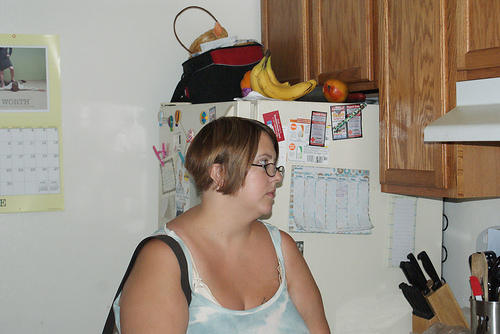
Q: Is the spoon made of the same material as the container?
A: Yes, both the spoon and the container are made of wood.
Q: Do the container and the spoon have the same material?
A: Yes, both the container and the spoon are made of wood.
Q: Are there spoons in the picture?
A: Yes, there is a spoon.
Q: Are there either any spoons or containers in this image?
A: Yes, there is a spoon.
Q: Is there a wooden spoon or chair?
A: Yes, there is a wood spoon.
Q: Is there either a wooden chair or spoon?
A: Yes, there is a wood spoon.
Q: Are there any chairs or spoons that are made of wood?
A: Yes, the spoon is made of wood.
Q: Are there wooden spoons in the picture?
A: Yes, there is a wood spoon.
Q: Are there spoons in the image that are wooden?
A: Yes, there is a spoon that is wooden.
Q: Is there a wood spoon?
A: Yes, there is a spoon that is made of wood.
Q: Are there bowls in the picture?
A: No, there are no bowls.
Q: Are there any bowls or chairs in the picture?
A: No, there are no bowls or chairs.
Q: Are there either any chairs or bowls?
A: No, there are no bowls or chairs.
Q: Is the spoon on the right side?
A: Yes, the spoon is on the right of the image.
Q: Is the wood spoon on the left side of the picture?
A: No, the spoon is on the right of the image.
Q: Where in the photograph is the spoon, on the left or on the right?
A: The spoon is on the right of the image.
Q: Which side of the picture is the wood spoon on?
A: The spoon is on the right of the image.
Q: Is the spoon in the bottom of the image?
A: Yes, the spoon is in the bottom of the image.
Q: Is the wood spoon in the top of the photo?
A: No, the spoon is in the bottom of the image.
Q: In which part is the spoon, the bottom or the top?
A: The spoon is in the bottom of the image.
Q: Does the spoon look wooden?
A: Yes, the spoon is wooden.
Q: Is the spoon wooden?
A: Yes, the spoon is wooden.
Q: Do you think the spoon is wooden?
A: Yes, the spoon is wooden.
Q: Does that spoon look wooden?
A: Yes, the spoon is wooden.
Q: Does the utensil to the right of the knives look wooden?
A: Yes, the spoon is wooden.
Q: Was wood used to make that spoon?
A: Yes, the spoon is made of wood.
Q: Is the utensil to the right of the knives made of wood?
A: Yes, the spoon is made of wood.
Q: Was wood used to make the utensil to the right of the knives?
A: Yes, the spoon is made of wood.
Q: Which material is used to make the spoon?
A: The spoon is made of wood.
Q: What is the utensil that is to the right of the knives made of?
A: The spoon is made of wood.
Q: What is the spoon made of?
A: The spoon is made of wood.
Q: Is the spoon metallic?
A: No, the spoon is wooden.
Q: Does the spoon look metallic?
A: No, the spoon is wooden.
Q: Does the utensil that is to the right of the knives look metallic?
A: No, the spoon is wooden.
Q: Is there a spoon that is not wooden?
A: No, there is a spoon but it is wooden.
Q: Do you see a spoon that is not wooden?
A: No, there is a spoon but it is wooden.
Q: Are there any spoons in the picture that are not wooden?
A: No, there is a spoon but it is wooden.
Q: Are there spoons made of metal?
A: No, there is a spoon but it is made of wood.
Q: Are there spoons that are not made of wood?
A: No, there is a spoon but it is made of wood.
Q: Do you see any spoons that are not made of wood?
A: No, there is a spoon but it is made of wood.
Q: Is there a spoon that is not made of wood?
A: No, there is a spoon but it is made of wood.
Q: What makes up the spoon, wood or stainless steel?
A: The spoon is made of wood.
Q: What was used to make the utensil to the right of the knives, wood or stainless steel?
A: The spoon is made of wood.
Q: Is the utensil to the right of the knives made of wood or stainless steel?
A: The spoon is made of wood.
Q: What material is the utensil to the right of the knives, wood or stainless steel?
A: The spoon is made of wood.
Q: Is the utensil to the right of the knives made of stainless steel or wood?
A: The spoon is made of wood.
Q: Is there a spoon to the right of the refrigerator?
A: Yes, there is a spoon to the right of the refrigerator.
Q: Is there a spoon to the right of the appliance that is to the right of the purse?
A: Yes, there is a spoon to the right of the refrigerator.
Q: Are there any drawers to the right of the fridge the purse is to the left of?
A: No, there is a spoon to the right of the freezer.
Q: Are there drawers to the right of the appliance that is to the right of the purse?
A: No, there is a spoon to the right of the freezer.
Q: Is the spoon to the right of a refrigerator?
A: Yes, the spoon is to the right of a refrigerator.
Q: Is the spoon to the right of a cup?
A: No, the spoon is to the right of a refrigerator.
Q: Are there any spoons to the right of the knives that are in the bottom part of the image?
A: Yes, there is a spoon to the right of the knives.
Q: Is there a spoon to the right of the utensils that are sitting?
A: Yes, there is a spoon to the right of the knives.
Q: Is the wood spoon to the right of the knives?
A: Yes, the spoon is to the right of the knives.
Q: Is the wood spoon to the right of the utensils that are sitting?
A: Yes, the spoon is to the right of the knives.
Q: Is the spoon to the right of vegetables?
A: No, the spoon is to the right of the knives.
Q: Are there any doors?
A: Yes, there is a door.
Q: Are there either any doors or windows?
A: Yes, there is a door.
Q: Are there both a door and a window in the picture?
A: No, there is a door but no windows.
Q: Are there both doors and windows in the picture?
A: No, there is a door but no windows.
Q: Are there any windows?
A: No, there are no windows.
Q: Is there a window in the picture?
A: No, there are no windows.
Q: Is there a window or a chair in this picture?
A: No, there are no windows or chairs.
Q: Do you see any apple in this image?
A: Yes, there is an apple.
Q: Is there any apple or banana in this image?
A: Yes, there is an apple.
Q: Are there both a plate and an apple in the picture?
A: No, there is an apple but no plates.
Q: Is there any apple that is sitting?
A: Yes, there is an apple that is sitting.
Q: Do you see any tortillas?
A: No, there are no tortillas.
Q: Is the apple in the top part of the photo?
A: Yes, the apple is in the top of the image.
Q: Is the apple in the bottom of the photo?
A: No, the apple is in the top of the image.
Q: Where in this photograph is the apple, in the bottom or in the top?
A: The apple is in the top of the image.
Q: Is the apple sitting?
A: Yes, the apple is sitting.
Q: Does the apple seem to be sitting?
A: Yes, the apple is sitting.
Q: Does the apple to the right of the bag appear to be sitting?
A: Yes, the apple is sitting.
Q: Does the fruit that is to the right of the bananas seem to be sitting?
A: Yes, the apple is sitting.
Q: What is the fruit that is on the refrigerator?
A: The fruit is an apple.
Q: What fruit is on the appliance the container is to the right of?
A: The fruit is an apple.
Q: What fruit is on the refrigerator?
A: The fruit is an apple.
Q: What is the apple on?
A: The apple is on the refrigerator.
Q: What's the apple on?
A: The apple is on the refrigerator.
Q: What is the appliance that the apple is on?
A: The appliance is a refrigerator.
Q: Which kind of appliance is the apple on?
A: The apple is on the refrigerator.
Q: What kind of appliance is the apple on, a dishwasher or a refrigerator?
A: The apple is on a refrigerator.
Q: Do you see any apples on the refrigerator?
A: Yes, there is an apple on the refrigerator.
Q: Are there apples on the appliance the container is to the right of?
A: Yes, there is an apple on the refrigerator.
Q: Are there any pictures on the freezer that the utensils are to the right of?
A: No, there is an apple on the refrigerator.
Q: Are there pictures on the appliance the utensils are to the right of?
A: No, there is an apple on the refrigerator.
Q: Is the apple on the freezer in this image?
A: Yes, the apple is on the freezer.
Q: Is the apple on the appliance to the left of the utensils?
A: Yes, the apple is on the freezer.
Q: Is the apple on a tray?
A: No, the apple is on the freezer.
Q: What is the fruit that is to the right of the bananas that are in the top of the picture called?
A: The fruit is an apple.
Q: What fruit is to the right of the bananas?
A: The fruit is an apple.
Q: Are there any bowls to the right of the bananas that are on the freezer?
A: No, there is an apple to the right of the bananas.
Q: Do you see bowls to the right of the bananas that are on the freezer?
A: No, there is an apple to the right of the bananas.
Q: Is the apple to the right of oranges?
A: No, the apple is to the right of the bananas.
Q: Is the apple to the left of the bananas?
A: No, the apple is to the right of the bananas.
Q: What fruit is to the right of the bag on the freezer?
A: The fruit is an apple.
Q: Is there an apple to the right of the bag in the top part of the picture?
A: Yes, there is an apple to the right of the bag.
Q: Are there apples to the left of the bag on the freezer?
A: No, the apple is to the right of the bag.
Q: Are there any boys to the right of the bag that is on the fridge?
A: No, there is an apple to the right of the bag.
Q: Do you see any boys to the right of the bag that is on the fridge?
A: No, there is an apple to the right of the bag.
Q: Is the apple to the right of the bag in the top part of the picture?
A: Yes, the apple is to the right of the bag.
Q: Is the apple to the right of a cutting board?
A: No, the apple is to the right of the bag.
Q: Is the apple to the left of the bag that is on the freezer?
A: No, the apple is to the right of the bag.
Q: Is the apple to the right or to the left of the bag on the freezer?
A: The apple is to the right of the bag.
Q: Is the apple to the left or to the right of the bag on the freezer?
A: The apple is to the right of the bag.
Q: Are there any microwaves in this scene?
A: No, there are no microwaves.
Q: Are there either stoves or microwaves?
A: No, there are no microwaves or stoves.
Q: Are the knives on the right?
A: Yes, the knives are on the right of the image.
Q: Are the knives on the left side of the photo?
A: No, the knives are on the right of the image.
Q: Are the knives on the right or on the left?
A: The knives are on the right of the image.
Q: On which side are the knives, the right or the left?
A: The knives are on the right of the image.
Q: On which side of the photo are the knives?
A: The knives are on the right of the image.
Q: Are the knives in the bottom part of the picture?
A: Yes, the knives are in the bottom of the image.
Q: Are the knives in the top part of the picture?
A: No, the knives are in the bottom of the image.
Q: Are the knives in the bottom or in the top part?
A: The knives are in the bottom of the image.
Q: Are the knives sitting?
A: Yes, the knives are sitting.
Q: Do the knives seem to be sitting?
A: Yes, the knives are sitting.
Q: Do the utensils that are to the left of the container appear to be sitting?
A: Yes, the knives are sitting.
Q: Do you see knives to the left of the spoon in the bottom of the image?
A: Yes, there are knives to the left of the spoon.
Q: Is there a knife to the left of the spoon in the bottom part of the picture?
A: Yes, there are knives to the left of the spoon.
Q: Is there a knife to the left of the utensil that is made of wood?
A: Yes, there are knives to the left of the spoon.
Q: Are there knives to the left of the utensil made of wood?
A: Yes, there are knives to the left of the spoon.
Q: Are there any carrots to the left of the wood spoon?
A: No, there are knives to the left of the spoon.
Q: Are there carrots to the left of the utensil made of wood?
A: No, there are knives to the left of the spoon.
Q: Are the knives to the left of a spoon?
A: Yes, the knives are to the left of a spoon.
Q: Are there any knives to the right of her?
A: Yes, there are knives to the right of the lady.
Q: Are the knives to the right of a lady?
A: Yes, the knives are to the right of a lady.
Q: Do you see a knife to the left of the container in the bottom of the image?
A: Yes, there are knives to the left of the container.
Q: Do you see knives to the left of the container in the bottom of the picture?
A: Yes, there are knives to the left of the container.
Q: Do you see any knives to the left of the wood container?
A: Yes, there are knives to the left of the container.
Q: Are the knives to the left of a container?
A: Yes, the knives are to the left of a container.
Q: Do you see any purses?
A: Yes, there is a purse.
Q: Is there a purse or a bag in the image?
A: Yes, there is a purse.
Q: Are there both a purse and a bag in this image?
A: Yes, there are both a purse and a bag.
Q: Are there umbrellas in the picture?
A: No, there are no umbrellas.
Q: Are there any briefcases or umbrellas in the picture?
A: No, there are no umbrellas or briefcases.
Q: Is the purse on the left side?
A: Yes, the purse is on the left of the image.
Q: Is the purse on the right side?
A: No, the purse is on the left of the image.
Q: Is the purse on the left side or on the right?
A: The purse is on the left of the image.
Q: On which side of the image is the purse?
A: The purse is on the left of the image.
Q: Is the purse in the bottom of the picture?
A: Yes, the purse is in the bottom of the image.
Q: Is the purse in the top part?
A: No, the purse is in the bottom of the image.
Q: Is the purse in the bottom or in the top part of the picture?
A: The purse is in the bottom of the image.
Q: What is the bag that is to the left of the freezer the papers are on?
A: The bag is a purse.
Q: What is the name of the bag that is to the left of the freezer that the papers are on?
A: The bag is a purse.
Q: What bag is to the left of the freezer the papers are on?
A: The bag is a purse.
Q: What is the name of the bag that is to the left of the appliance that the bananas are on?
A: The bag is a purse.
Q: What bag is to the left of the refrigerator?
A: The bag is a purse.